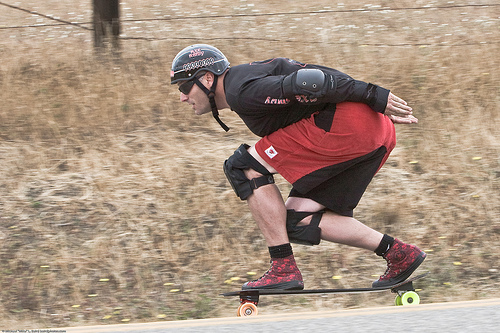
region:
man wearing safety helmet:
[158, 30, 233, 122]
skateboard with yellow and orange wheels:
[215, 285, 445, 317]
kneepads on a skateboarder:
[163, 32, 450, 319]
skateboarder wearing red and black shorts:
[158, 30, 444, 310]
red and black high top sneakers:
[215, 235, 442, 296]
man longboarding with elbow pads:
[153, 22, 446, 309]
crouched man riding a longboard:
[168, 29, 457, 311]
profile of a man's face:
[145, 25, 252, 134]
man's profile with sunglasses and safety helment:
[148, 23, 236, 120]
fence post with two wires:
[77, 3, 172, 60]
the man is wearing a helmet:
[169, 43, 232, 89]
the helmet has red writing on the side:
[180, 46, 208, 57]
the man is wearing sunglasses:
[170, 76, 215, 95]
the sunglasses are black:
[175, 83, 205, 93]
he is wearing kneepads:
[223, 145, 279, 200]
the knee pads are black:
[214, 143, 276, 205]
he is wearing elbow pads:
[287, 69, 337, 101]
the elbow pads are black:
[276, 69, 338, 100]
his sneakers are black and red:
[239, 256, 304, 291]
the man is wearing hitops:
[239, 257, 316, 294]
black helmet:
[154, 52, 232, 107]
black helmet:
[170, 42, 237, 92]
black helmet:
[151, 7, 238, 145]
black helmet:
[185, 37, 233, 122]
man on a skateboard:
[152, 12, 450, 296]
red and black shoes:
[232, 237, 419, 299]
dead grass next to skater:
[91, 189, 193, 260]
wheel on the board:
[227, 300, 261, 332]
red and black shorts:
[298, 111, 397, 196]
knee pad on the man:
[190, 135, 267, 213]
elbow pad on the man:
[280, 58, 342, 112]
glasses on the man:
[164, 65, 211, 106]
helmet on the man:
[171, 26, 243, 86]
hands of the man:
[384, 81, 424, 126]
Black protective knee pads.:
[211, 146, 341, 243]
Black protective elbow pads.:
[285, 65, 335, 106]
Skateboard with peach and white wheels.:
[208, 282, 465, 314]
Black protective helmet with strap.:
[152, 30, 229, 93]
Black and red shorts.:
[260, 105, 395, 204]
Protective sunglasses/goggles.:
[173, 73, 193, 98]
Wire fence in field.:
[157, 0, 474, 45]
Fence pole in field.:
[75, 4, 132, 101]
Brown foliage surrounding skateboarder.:
[25, 81, 177, 288]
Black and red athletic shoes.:
[220, 195, 435, 293]